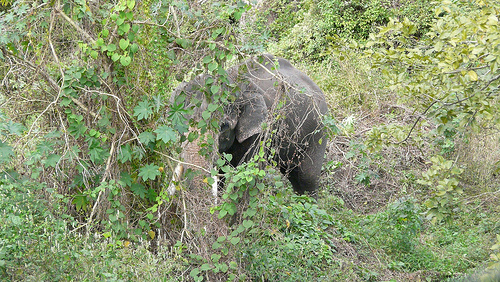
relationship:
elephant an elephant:
[163, 54, 335, 232] [113, 99, 361, 272]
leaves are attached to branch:
[70, 95, 160, 213] [100, 6, 225, 256]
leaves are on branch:
[97, 37, 140, 68] [79, 61, 132, 231]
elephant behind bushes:
[206, 56, 352, 198] [66, 45, 204, 218]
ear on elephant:
[235, 86, 270, 150] [175, 73, 302, 179]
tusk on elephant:
[153, 173, 203, 197] [197, 62, 307, 201]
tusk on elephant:
[211, 162, 243, 224] [155, 59, 326, 193]